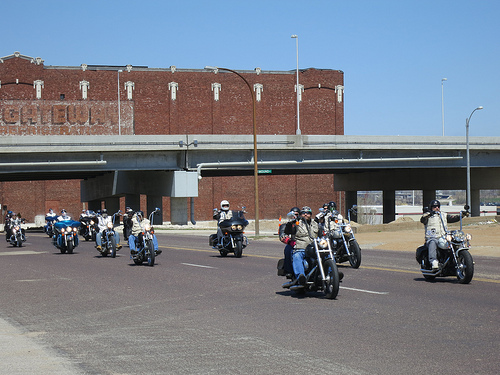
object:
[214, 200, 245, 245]
man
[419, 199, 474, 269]
person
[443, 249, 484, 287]
tyre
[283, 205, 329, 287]
person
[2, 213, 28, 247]
motorcycle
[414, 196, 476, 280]
motorcycle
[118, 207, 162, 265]
motorcycle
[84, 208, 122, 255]
motorcycle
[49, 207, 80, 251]
motorcycle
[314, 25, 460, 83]
sky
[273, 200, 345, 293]
motorcycle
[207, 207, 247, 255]
bike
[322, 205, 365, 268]
motorcycle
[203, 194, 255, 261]
setting sun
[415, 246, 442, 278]
bikes back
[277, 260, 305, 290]
bikes back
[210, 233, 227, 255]
bikes back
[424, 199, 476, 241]
handlebars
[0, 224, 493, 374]
road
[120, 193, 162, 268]
bike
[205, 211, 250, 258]
motorcycle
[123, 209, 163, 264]
person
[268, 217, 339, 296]
bike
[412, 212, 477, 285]
bike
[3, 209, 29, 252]
bike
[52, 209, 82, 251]
bike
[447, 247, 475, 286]
tire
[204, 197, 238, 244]
person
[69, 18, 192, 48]
clouds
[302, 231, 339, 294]
front